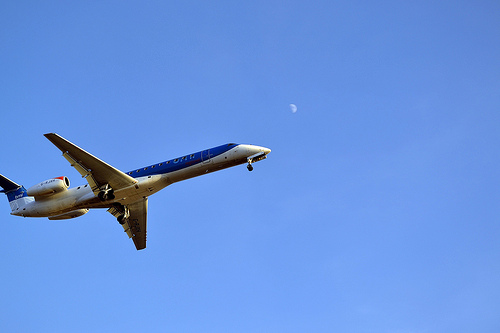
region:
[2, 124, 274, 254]
a jet airplane in the sky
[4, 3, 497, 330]
sky is clear and blue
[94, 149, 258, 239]
the landing gear is down on the airplane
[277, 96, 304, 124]
the moon is in the sky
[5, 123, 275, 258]
plane is blue white and red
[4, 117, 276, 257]
airplane is flying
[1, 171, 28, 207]
tail of an airplane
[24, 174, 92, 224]
jets on an airplane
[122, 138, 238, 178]
windows on the side of an airplane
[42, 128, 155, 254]
wings of an airplane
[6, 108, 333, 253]
Jet plane in flight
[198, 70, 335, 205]
Jet plane in front of moon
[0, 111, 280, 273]
Blue and white jet plane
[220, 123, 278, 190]
Plane nose and landing gear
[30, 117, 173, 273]
Wings of jet plane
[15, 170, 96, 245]
Engine of jet plane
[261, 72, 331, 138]
Moon in distance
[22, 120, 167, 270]
Engines and wings of jet plane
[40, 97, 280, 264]
Jet plane with landing gear down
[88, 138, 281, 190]
body of jet plane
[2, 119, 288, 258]
A blue and white plane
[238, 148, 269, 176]
Front landing gear of a plane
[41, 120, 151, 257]
The wings of a plane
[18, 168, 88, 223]
Jet engines on a plane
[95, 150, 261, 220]
Landing gear on a plane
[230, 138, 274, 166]
The nose of a plane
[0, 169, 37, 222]
Tail section of a plane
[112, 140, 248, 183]
Blue paint on a white plane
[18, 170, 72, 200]
A white jet engine with red trim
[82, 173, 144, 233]
Back landing gear.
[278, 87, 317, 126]
the daytime moon in the sky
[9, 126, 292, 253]
a blue and white plane in the sky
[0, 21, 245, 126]
clear blue skies above the plane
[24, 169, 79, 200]
a red and white engine of a plane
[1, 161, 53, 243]
the blue and white tail of the plane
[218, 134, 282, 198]
the front landing gear of the plane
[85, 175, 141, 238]
the center landing gear of the plane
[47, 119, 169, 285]
the wings of the plane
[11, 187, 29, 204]
the logo of the owner of the plane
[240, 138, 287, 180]
the white nose of the plane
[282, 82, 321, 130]
a soft white moon in the sky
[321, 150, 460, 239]
a clear blue morning sky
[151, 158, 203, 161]
windows in the plane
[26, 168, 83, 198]
an engine on the side of the plane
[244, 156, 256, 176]
black rubber front wheels of the plane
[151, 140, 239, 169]
blue top of the plane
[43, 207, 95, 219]
right wing engine of the plane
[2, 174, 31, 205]
large tail fin on the plane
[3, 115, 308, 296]
a commercial plane taking off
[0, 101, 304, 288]
a large passenger plane preparing to land